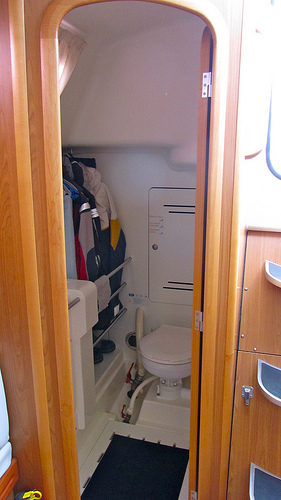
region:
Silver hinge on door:
[201, 74, 212, 97]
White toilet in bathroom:
[138, 315, 200, 399]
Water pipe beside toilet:
[134, 306, 146, 380]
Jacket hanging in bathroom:
[83, 165, 129, 281]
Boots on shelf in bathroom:
[89, 334, 116, 363]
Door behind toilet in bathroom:
[145, 185, 199, 306]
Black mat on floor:
[88, 423, 189, 497]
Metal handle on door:
[242, 383, 252, 406]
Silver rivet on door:
[242, 284, 250, 293]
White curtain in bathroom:
[53, 25, 84, 100]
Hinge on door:
[199, 70, 214, 100]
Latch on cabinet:
[240, 384, 254, 406]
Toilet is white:
[137, 321, 191, 405]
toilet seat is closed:
[137, 321, 192, 365]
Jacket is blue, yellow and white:
[82, 162, 126, 271]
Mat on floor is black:
[78, 433, 192, 499]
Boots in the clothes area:
[91, 331, 115, 365]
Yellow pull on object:
[20, 489, 44, 499]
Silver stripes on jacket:
[78, 199, 99, 219]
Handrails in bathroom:
[68, 257, 132, 313]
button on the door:
[237, 284, 257, 295]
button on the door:
[249, 344, 261, 350]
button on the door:
[250, 345, 261, 355]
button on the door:
[238, 332, 244, 342]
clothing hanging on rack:
[86, 165, 116, 251]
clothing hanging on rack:
[92, 209, 108, 266]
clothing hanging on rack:
[83, 203, 97, 259]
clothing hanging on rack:
[68, 183, 79, 204]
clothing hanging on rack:
[65, 177, 80, 207]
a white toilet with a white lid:
[135, 310, 197, 404]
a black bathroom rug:
[81, 431, 200, 498]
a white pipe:
[128, 298, 147, 389]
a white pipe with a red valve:
[120, 372, 166, 421]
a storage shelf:
[249, 241, 280, 287]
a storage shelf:
[253, 356, 279, 403]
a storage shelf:
[241, 456, 279, 498]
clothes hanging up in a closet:
[58, 144, 135, 327]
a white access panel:
[141, 179, 204, 307]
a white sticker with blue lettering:
[123, 286, 152, 311]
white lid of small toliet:
[151, 315, 194, 368]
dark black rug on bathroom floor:
[113, 444, 157, 496]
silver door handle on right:
[239, 381, 255, 407]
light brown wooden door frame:
[15, 263, 64, 381]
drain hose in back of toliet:
[133, 306, 146, 379]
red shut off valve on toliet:
[120, 356, 132, 378]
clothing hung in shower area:
[68, 155, 111, 234]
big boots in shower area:
[92, 335, 118, 357]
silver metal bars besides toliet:
[111, 266, 137, 297]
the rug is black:
[154, 456, 174, 465]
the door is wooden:
[187, 443, 198, 454]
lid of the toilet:
[133, 330, 185, 357]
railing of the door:
[202, 75, 210, 99]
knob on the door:
[238, 385, 256, 407]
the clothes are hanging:
[84, 197, 112, 241]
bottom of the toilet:
[152, 379, 177, 393]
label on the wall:
[145, 212, 166, 230]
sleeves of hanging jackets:
[63, 155, 126, 318]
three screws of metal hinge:
[201, 72, 210, 98]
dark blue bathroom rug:
[82, 434, 189, 498]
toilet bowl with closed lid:
[139, 325, 191, 376]